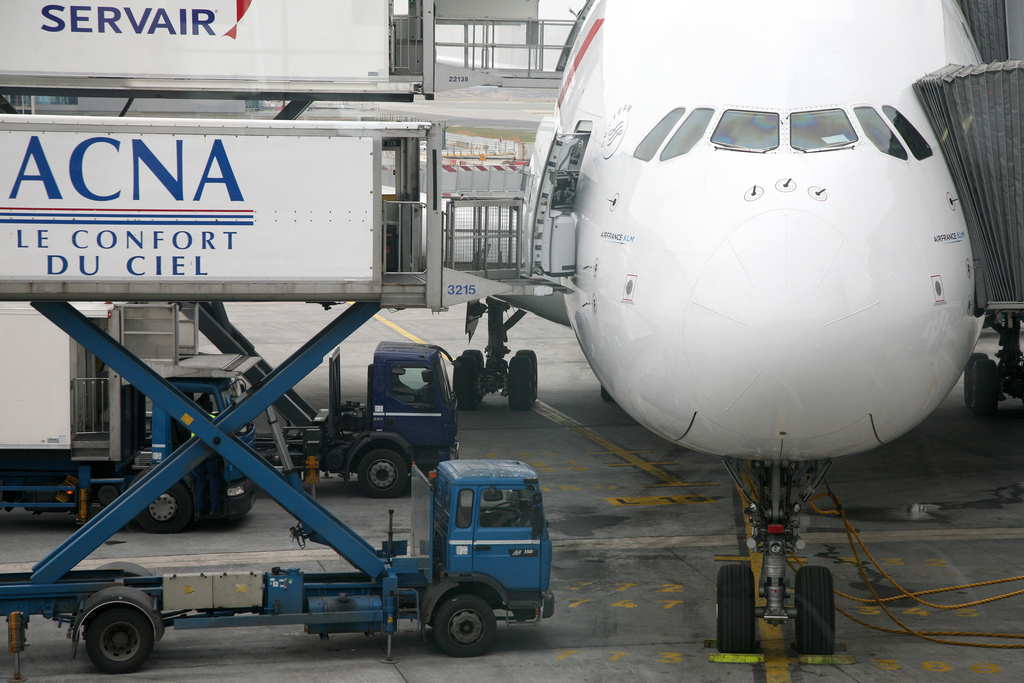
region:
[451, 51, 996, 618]
Plane on the runway.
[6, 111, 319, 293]
Blue words on the truck.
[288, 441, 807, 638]
Blue truck on the road.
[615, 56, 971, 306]
Windows on the plane.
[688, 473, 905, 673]
Wheels on the plane.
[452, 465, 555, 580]
Window on the truck.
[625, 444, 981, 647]
Black wheels on the plane.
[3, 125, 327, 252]
ACNA on the truck.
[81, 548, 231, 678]
Wheels on the truck.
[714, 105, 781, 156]
The plane has a window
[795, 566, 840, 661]
The plane has a wheel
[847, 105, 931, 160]
The plane has a window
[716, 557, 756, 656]
The plane has a wheel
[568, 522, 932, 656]
Water is on the cement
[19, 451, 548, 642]
The truck is blue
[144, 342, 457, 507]
The truck is blue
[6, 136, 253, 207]
The word ACNA is on the trailer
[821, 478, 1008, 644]
The cord is yellow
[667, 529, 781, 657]
Wheels on the plane.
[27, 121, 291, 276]
Blue letters on the truck.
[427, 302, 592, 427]
Big wheels on the plane.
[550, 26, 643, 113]
White and blue and red stripes.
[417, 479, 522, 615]
Door on the truck.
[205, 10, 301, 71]
Red part on the truck.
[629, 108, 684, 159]
glass window on the plane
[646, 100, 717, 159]
glass window on the plane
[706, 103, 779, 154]
glass window on the plane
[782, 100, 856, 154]
glass window on the plane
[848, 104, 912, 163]
glass window on the plane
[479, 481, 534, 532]
Window of a vehicle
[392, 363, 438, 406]
Window of a vehicle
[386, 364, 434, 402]
Window of a vehicle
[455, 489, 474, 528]
Window of a vehicle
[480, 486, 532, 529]
Window of a vehicle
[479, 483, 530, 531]
Window of a blue vehicle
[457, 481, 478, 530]
Window of a blue vehicle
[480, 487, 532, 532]
Window of a blue vehicle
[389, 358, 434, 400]
Window of a vehicle